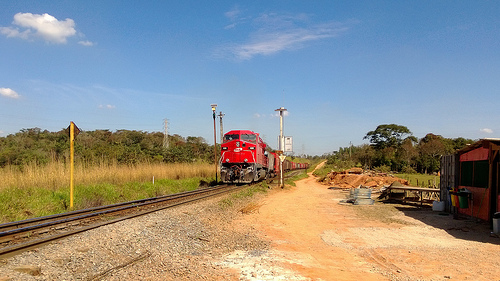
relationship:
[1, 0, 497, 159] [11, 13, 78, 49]
sky has clouds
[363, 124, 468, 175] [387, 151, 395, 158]
trees have leaves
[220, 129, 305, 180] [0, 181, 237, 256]
train going down railway line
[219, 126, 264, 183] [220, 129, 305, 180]
front car of train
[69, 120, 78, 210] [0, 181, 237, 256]
pole next to railway line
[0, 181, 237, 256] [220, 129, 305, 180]
railway line ahead of train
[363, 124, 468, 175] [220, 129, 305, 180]
trees right of train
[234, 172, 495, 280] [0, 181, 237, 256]
dirt next to railway line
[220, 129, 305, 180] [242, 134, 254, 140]
train has window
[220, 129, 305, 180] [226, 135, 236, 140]
train has window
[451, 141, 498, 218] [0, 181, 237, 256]
building next to railway line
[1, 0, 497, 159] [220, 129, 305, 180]
sky above train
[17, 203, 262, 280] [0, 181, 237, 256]
gravel next to railway line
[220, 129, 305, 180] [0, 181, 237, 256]
train on top of railway line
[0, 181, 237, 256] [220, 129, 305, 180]
railway line in front of train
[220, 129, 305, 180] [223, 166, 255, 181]
train has wheels